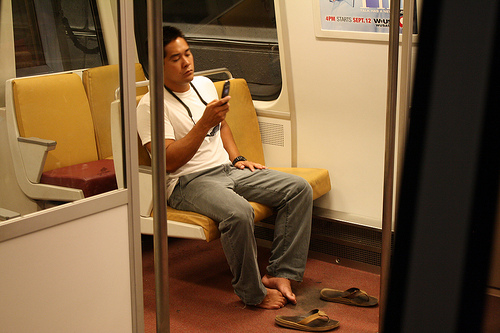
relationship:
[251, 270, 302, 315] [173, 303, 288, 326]
feet on floor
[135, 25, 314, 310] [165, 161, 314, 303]
man wearing jeans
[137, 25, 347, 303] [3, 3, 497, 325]
man sitting on subway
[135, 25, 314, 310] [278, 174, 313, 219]
man has knee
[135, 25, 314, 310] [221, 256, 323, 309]
man has feet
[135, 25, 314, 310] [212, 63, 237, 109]
man with phone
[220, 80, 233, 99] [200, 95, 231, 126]
cell phone in hand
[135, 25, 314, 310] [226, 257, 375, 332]
man with foot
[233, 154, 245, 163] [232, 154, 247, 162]
watch on wrist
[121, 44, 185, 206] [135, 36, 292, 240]
pole across from man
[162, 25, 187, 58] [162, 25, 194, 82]
hair on head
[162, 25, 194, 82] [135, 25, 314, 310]
head on man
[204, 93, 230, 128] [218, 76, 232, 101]
hand holding phone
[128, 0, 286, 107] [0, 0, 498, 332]
window on subway